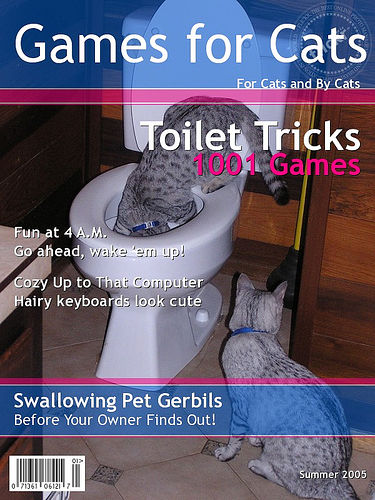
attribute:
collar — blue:
[229, 323, 272, 341]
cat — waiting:
[206, 269, 374, 496]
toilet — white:
[69, 19, 296, 398]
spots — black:
[260, 352, 304, 379]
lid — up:
[130, 3, 277, 161]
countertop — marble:
[0, 224, 52, 319]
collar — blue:
[131, 222, 163, 230]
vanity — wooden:
[2, 316, 60, 500]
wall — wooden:
[5, 9, 97, 273]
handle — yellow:
[295, 99, 309, 248]